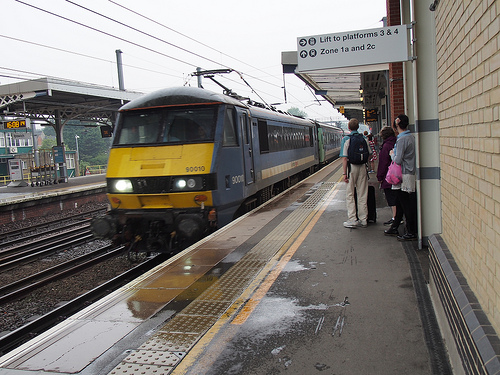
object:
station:
[0, 120, 108, 205]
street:
[0, 173, 109, 204]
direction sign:
[297, 24, 408, 72]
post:
[403, 0, 439, 237]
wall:
[385, 4, 497, 374]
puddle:
[18, 241, 328, 375]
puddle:
[251, 182, 347, 216]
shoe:
[397, 234, 418, 241]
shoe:
[384, 229, 399, 236]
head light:
[176, 179, 195, 189]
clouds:
[0, 0, 386, 124]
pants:
[345, 164, 368, 226]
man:
[339, 119, 373, 228]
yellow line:
[169, 178, 347, 375]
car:
[90, 87, 350, 263]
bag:
[385, 160, 403, 185]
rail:
[0, 204, 164, 352]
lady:
[376, 126, 405, 225]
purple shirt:
[376, 136, 397, 189]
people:
[339, 114, 418, 240]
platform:
[0, 157, 452, 375]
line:
[70, 20, 119, 40]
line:
[126, 23, 164, 42]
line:
[168, 28, 211, 49]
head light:
[115, 179, 133, 192]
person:
[384, 114, 418, 241]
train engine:
[92, 68, 320, 264]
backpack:
[344, 133, 369, 165]